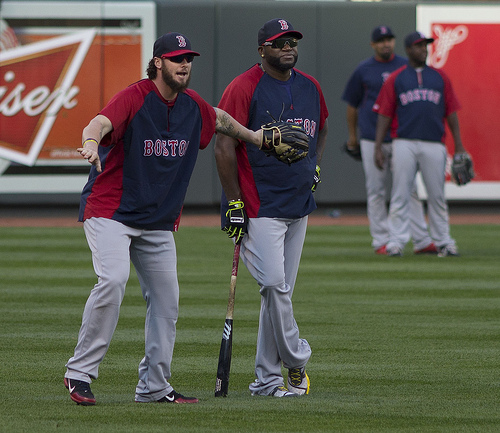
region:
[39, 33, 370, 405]
The men are standing on the field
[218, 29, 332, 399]
The man is leaning on a baseball bat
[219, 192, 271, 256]
The man is wearing black and yellow gloves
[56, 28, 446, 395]
The men are wearing blue and red jerseys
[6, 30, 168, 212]
Orange and white sign on wall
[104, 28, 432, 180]
The green wall has panels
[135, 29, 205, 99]
The man is wearing sunglasses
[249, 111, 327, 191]
The man is wearing a mitt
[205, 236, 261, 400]
The bat is black, brown, and red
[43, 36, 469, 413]
The men are wearing grey pants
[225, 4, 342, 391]
the man is playing baseball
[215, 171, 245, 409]
the man is holding a baseball bat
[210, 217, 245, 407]
the bat is made of wood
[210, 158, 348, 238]
the man is wearing gloves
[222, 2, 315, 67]
the man is wearing sunglasses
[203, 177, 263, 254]
the gloves are black and green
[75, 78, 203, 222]
the jerseys say boston on the front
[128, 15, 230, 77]
the man is wearing a baseball hat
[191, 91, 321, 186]
the glove is black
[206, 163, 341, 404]
the man`s leg is crossed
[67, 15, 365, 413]
Men on field playing baseball.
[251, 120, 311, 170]
Player wearing mitt on left hand.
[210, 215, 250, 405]
Player leaning on baseball bat.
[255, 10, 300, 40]
Player wearing navy blue and red baseball cap.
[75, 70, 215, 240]
Player wearing navy blue and red shirt.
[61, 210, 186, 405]
Player dressed in gray pants.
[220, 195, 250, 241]
Player wearing black glove trimmed in yellow.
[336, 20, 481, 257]
Two players standing on edge of playing field.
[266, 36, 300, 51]
Baseball player wearing sunglasses over eyes.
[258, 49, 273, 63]
Man wearing gold stud earring in ear.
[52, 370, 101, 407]
red and black rubber shoes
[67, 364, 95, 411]
red and black rubber shoes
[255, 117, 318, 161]
The black and brown glove on the player's hand on the left.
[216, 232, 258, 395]
The bat the player is leaning on.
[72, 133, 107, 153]
The bracelet on the player's wrist on the left.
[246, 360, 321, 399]
The black and yellow sneakers the player leaning on the bat is wearing.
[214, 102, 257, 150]
The tattoos on the arm of the player on the left.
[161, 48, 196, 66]
The black sunglasses the player on the left is wearing.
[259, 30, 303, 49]
The sunglasses on the player on the right.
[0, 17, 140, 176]
The billboard behind the player on the left.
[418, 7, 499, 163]
The billboard on the right behind the players.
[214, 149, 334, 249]
The yellow and black gloves the player on the right is wearing.